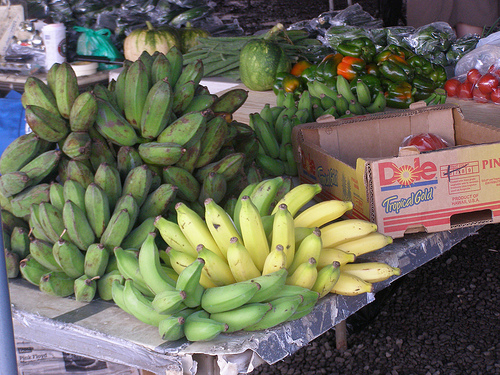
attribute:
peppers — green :
[351, 40, 451, 102]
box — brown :
[292, 101, 499, 238]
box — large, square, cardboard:
[294, 97, 497, 250]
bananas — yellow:
[159, 186, 386, 304]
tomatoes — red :
[402, 47, 494, 123]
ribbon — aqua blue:
[76, 21, 123, 61]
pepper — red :
[362, 121, 457, 182]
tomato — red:
[476, 72, 498, 96]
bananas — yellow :
[89, 160, 429, 315]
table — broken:
[12, 79, 490, 373]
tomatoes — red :
[446, 65, 499, 105]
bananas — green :
[28, 40, 454, 358]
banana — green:
[211, 280, 250, 312]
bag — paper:
[458, 41, 498, 76]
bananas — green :
[92, 48, 213, 168]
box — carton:
[305, 83, 492, 251]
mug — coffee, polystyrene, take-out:
[41, 21, 66, 72]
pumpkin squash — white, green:
[124, 22, 180, 62]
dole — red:
[378, 156, 438, 188]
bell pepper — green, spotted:
[374, 51, 417, 81]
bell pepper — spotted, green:
[338, 30, 377, 59]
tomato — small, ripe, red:
[443, 77, 459, 94]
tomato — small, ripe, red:
[453, 78, 469, 96]